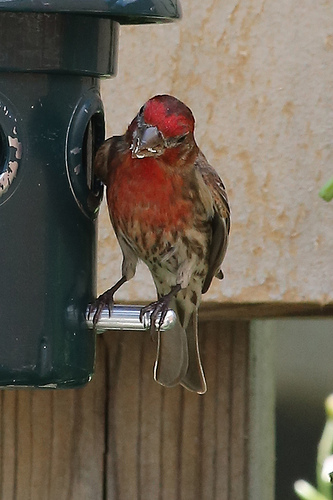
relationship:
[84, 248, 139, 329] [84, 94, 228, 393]
leg of bird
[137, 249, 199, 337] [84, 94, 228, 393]
leg of bird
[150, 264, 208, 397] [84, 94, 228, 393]
tail of bird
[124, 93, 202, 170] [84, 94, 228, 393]
head of bird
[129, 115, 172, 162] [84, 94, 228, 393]
peak of bird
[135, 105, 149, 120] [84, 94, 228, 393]
eye of bird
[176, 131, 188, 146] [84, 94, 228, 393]
eye of bird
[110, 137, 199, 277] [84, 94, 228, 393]
chest of bird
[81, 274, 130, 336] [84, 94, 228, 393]
foot of bird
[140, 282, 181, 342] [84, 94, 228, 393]
foot of bird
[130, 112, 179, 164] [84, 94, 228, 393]
beak of bird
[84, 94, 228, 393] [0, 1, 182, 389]
bird on feeder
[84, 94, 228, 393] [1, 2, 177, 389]
bird on birdhouse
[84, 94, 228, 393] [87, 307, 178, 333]
bird perched handle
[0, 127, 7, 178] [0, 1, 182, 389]
hole in feeder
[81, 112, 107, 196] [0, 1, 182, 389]
hole in feeder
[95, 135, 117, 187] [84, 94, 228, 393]
wing of bird